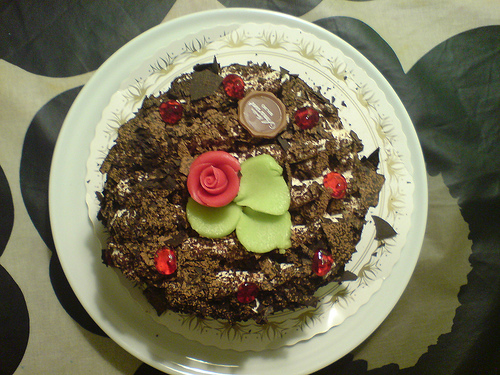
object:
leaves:
[237, 211, 294, 251]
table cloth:
[2, 4, 497, 370]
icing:
[96, 65, 380, 324]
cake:
[96, 61, 383, 324]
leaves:
[186, 205, 239, 244]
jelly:
[156, 248, 173, 272]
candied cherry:
[320, 166, 351, 197]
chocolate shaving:
[181, 62, 215, 100]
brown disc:
[231, 89, 291, 137]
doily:
[82, 20, 419, 348]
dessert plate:
[50, 7, 424, 375]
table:
[1, 2, 500, 375]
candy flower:
[187, 151, 242, 209]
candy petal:
[237, 154, 294, 217]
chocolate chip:
[290, 107, 319, 132]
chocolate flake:
[372, 214, 395, 249]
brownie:
[123, 119, 198, 156]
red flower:
[320, 171, 351, 198]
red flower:
[311, 246, 339, 272]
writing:
[246, 99, 280, 130]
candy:
[158, 96, 185, 124]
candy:
[222, 73, 250, 100]